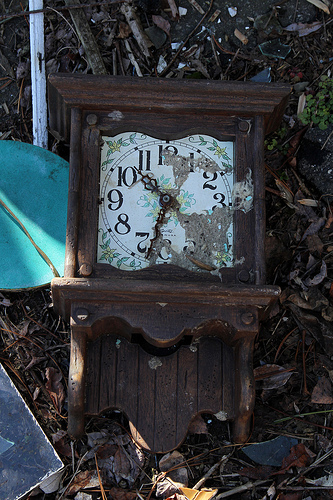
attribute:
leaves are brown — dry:
[1, 1, 332, 499]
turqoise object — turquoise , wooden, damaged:
[49, 72, 295, 451]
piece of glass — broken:
[1, 363, 66, 497]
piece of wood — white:
[46, 72, 291, 448]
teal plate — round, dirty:
[0, 140, 70, 289]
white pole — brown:
[29, 0, 48, 147]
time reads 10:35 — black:
[96, 129, 240, 268]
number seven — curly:
[133, 231, 153, 258]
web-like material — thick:
[95, 128, 243, 271]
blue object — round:
[1, 139, 69, 292]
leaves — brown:
[83, 441, 317, 499]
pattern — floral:
[176, 183, 211, 229]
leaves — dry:
[7, 0, 332, 498]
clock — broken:
[45, 68, 294, 456]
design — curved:
[68, 397, 249, 452]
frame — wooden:
[45, 69, 293, 455]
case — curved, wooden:
[44, 68, 289, 453]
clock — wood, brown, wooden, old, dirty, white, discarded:
[97, 132, 235, 277]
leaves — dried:
[1, 349, 332, 497]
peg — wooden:
[74, 307, 89, 319]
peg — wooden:
[239, 308, 255, 324]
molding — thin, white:
[27, 2, 49, 151]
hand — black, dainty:
[133, 163, 178, 208]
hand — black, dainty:
[142, 190, 169, 259]